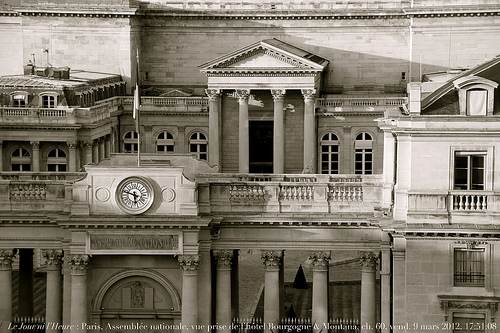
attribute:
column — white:
[205, 88, 221, 171]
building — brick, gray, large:
[1, 1, 499, 331]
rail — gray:
[199, 182, 380, 217]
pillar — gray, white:
[231, 90, 251, 174]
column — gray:
[260, 251, 284, 332]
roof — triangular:
[196, 39, 330, 73]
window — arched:
[319, 133, 341, 174]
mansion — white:
[2, 1, 499, 331]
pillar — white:
[270, 91, 286, 173]